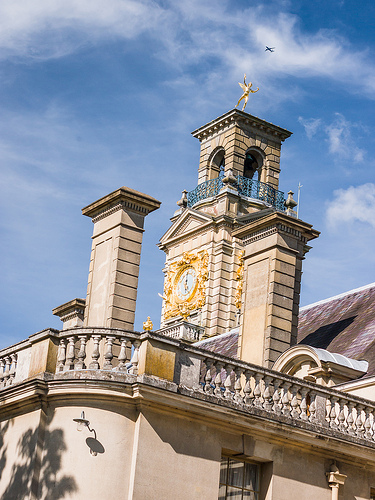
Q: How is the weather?
A: It is sunny.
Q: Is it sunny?
A: Yes, it is sunny.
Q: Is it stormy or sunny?
A: It is sunny.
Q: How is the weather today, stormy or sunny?
A: It is sunny.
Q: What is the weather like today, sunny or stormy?
A: It is sunny.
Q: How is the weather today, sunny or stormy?
A: It is sunny.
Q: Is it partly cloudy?
A: No, it is sunny.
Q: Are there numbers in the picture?
A: Yes, there are numbers.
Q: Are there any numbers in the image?
A: Yes, there are numbers.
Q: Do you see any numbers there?
A: Yes, there are numbers.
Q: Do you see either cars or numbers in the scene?
A: Yes, there are numbers.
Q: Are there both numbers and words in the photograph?
A: No, there are numbers but no words.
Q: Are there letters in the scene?
A: No, there are no letters.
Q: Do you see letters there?
A: No, there are no letters.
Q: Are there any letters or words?
A: No, there are no letters or words.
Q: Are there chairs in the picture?
A: No, there are no chairs.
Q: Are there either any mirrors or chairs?
A: No, there are no chairs or mirrors.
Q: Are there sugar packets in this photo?
A: No, there are no sugar packets.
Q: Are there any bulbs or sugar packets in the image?
A: No, there are no sugar packets or bulbs.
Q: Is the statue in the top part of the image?
A: Yes, the statue is in the top of the image.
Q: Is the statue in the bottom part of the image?
A: No, the statue is in the top of the image.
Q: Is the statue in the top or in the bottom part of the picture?
A: The statue is in the top of the image.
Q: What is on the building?
A: The statue is on the building.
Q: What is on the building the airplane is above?
A: The statue is on the building.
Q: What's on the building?
A: The statue is on the building.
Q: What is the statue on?
A: The statue is on the building.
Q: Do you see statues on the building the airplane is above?
A: Yes, there is a statue on the building.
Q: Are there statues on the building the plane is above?
A: Yes, there is a statue on the building.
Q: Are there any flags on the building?
A: No, there is a statue on the building.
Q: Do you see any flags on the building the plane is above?
A: No, there is a statue on the building.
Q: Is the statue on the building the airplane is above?
A: Yes, the statue is on the building.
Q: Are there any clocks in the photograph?
A: Yes, there is a clock.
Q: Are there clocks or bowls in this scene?
A: Yes, there is a clock.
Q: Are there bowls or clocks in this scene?
A: Yes, there is a clock.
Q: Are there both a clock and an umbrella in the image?
A: No, there is a clock but no umbrellas.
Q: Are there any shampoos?
A: No, there are no shampoos.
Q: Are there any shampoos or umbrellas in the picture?
A: No, there are no shampoos or umbrellas.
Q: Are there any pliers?
A: No, there are no pliers.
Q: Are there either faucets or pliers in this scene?
A: No, there are no pliers or faucets.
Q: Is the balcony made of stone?
A: Yes, the balcony is made of stone.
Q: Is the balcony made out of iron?
A: No, the balcony is made of stone.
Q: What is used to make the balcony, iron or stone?
A: The balcony is made of stone.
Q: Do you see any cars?
A: No, there are no cars.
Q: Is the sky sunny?
A: Yes, the sky is sunny.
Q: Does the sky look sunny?
A: Yes, the sky is sunny.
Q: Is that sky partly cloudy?
A: No, the sky is sunny.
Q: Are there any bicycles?
A: No, there are no bicycles.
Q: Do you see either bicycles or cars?
A: No, there are no bicycles or cars.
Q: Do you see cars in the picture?
A: No, there are no cars.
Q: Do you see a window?
A: Yes, there is a window.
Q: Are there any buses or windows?
A: Yes, there is a window.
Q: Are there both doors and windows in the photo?
A: No, there is a window but no doors.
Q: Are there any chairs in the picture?
A: No, there are no chairs.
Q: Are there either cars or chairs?
A: No, there are no chairs or cars.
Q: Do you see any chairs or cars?
A: No, there are no chairs or cars.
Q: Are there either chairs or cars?
A: No, there are no chairs or cars.